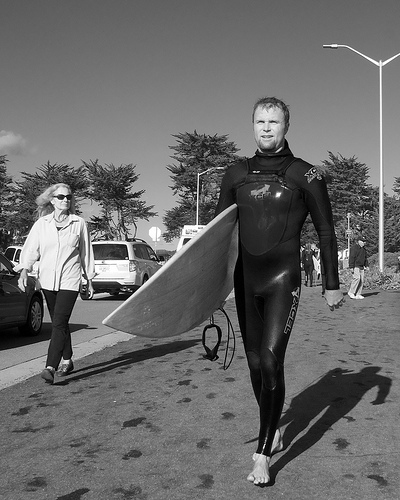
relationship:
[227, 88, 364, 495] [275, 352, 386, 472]
man with shadow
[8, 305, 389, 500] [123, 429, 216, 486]
footprints on ground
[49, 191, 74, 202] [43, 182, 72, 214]
sunglasses on face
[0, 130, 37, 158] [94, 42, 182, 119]
cloud in sky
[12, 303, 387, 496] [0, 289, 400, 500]
footprints on ground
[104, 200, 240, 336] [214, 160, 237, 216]
surfboard under man's arm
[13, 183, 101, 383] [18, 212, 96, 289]
woman in shirt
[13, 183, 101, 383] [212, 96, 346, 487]
woman walking next to man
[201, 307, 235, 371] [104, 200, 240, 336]
ankle strap attached to surfboard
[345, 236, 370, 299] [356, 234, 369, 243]
man in cap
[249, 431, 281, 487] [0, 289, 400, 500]
feet on ground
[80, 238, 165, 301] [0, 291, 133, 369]
car driving on road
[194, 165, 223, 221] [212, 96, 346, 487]
street lamp behind man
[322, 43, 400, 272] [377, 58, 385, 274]
lamp post on pole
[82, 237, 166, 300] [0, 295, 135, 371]
car on street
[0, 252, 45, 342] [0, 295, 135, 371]
car on street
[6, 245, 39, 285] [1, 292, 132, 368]
car on street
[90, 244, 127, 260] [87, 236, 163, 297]
window on a car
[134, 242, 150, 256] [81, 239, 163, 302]
window on a car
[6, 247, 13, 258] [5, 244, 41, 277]
window of a car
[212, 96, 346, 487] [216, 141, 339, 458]
man wearing a wetsuit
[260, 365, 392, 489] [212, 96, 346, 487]
shadow behind man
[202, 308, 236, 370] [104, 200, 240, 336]
ankle strap hanging from surfboard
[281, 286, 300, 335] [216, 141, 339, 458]
logo on wetsuit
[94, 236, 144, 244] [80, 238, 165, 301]
roof rack on top of car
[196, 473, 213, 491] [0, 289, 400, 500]
spot on top of ground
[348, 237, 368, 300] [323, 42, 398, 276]
man standing near lamp post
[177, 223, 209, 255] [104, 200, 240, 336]
van behind surfboard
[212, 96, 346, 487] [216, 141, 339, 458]
man wearing wetsuit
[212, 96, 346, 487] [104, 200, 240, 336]
man holding surfboard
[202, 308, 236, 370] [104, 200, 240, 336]
ankle strap on surfboard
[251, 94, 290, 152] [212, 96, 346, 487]
head on man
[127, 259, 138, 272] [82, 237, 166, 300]
tail light on car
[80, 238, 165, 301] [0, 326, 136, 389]
car on curb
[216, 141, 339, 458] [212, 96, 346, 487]
wetsuit on man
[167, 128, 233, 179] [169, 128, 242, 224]
leaves on tree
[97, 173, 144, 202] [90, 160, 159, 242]
leaves on tree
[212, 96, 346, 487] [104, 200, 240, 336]
man carrying surfboard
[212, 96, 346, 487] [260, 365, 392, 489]
man casting shadow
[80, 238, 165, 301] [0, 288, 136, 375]
car on road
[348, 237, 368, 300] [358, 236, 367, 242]
man wearing cap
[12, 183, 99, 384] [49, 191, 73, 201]
woman wearing sunglasses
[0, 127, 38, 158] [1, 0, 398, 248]
cloud in sky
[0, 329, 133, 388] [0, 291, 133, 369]
curb near road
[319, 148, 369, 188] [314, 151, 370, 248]
leaves on tree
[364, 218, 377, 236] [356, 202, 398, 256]
leaves on tree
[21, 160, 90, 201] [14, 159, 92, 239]
leaves on tree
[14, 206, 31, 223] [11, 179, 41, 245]
leaves on tree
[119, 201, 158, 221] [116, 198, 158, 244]
leaves on tree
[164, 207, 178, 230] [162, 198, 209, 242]
leaves on tree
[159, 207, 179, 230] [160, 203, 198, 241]
leaves on tree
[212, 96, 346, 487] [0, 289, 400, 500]
man walking down ground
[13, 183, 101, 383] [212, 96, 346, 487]
woman looking at man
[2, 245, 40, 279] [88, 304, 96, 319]
car on road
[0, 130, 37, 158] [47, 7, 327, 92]
cloud in sky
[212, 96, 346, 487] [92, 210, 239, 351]
man carrying surfboard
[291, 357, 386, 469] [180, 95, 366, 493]
shadow of man